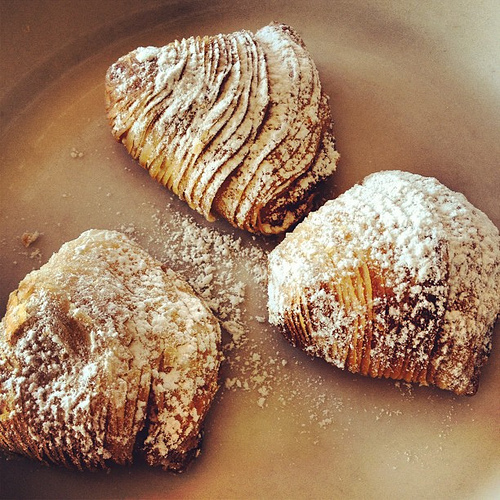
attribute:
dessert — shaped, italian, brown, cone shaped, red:
[101, 20, 337, 239]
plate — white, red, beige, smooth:
[0, 2, 500, 499]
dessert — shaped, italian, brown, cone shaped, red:
[262, 166, 499, 395]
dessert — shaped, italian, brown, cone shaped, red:
[0, 225, 225, 476]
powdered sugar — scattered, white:
[143, 200, 330, 427]